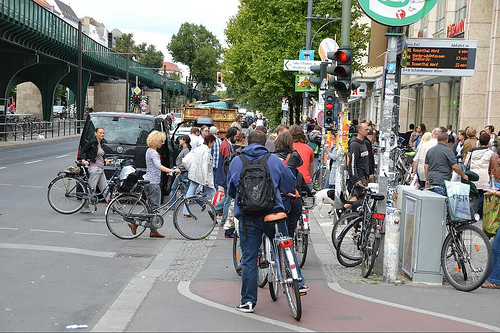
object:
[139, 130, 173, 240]
woman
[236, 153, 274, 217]
backpack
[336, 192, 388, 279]
bike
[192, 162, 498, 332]
sidewalk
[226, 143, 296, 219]
sweatshirt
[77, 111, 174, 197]
car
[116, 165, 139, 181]
dog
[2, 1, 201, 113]
bridge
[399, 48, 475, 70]
sign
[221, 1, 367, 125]
tree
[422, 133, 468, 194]
man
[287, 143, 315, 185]
shirt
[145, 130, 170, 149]
hair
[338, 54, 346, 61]
red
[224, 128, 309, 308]
person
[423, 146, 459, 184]
shirt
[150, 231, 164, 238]
boot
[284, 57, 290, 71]
arrow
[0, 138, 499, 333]
street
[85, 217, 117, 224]
spot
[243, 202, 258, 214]
black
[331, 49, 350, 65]
traffic light